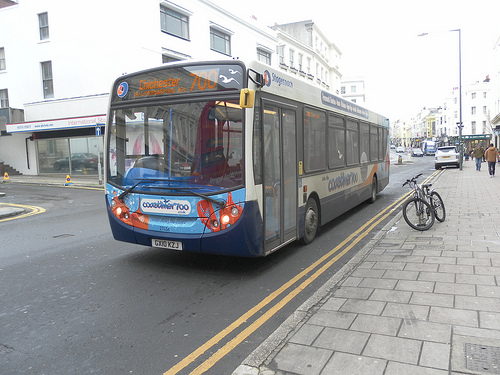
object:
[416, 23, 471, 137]
lamp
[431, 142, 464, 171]
car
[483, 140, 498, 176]
person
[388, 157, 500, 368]
sidewalk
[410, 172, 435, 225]
metal grate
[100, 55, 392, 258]
bus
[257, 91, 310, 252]
glass door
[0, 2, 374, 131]
building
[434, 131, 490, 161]
storefront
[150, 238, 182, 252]
license plate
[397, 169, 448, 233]
bike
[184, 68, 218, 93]
700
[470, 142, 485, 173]
people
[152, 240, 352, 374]
lines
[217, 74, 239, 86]
seagulls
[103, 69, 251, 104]
route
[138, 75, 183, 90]
chichester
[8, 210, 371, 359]
city street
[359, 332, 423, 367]
bricks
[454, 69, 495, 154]
buildings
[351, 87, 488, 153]
background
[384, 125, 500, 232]
halfway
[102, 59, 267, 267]
bus front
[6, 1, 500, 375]
city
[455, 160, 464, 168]
wheels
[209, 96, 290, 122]
lights